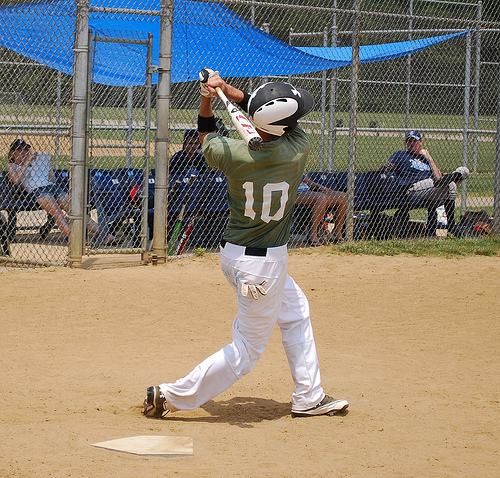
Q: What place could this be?
A: It is a field.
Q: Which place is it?
A: It is a field.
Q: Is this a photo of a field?
A: Yes, it is showing a field.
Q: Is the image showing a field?
A: Yes, it is showing a field.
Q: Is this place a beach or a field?
A: It is a field.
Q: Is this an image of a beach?
A: No, the picture is showing a field.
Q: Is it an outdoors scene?
A: Yes, it is outdoors.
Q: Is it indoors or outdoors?
A: It is outdoors.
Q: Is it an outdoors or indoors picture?
A: It is outdoors.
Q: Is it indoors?
A: No, it is outdoors.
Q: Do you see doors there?
A: Yes, there is a door.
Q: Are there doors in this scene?
A: Yes, there is a door.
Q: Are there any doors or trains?
A: Yes, there is a door.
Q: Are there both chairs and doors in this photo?
A: No, there is a door but no chairs.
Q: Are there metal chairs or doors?
A: Yes, there is a metal door.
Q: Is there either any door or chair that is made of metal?
A: Yes, the door is made of metal.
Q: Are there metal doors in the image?
A: Yes, there is a metal door.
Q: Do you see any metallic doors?
A: Yes, there is a metal door.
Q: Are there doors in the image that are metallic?
A: Yes, there is a door that is metallic.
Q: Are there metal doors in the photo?
A: Yes, there is a door that is made of metal.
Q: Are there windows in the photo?
A: No, there are no windows.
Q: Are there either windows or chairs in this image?
A: No, there are no windows or chairs.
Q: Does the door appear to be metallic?
A: Yes, the door is metallic.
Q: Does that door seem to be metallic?
A: Yes, the door is metallic.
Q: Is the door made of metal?
A: Yes, the door is made of metal.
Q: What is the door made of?
A: The door is made of metal.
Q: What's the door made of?
A: The door is made of metal.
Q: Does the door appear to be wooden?
A: No, the door is metallic.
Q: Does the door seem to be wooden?
A: No, the door is metallic.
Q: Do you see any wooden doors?
A: No, there is a door but it is metallic.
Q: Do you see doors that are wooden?
A: No, there is a door but it is metallic.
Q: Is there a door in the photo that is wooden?
A: No, there is a door but it is metallic.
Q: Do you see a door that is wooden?
A: No, there is a door but it is metallic.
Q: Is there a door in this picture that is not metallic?
A: No, there is a door but it is metallic.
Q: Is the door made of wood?
A: No, the door is made of metal.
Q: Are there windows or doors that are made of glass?
A: No, there is a door but it is made of metal.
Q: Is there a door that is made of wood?
A: No, there is a door but it is made of metal.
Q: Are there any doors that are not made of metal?
A: No, there is a door but it is made of metal.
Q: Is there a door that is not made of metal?
A: No, there is a door but it is made of metal.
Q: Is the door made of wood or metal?
A: The door is made of metal.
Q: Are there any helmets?
A: Yes, there is a helmet.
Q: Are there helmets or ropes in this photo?
A: Yes, there is a helmet.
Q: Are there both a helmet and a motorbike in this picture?
A: No, there is a helmet but no motorcycles.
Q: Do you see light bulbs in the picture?
A: No, there are no light bulbs.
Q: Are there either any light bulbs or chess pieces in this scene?
A: No, there are no light bulbs or chess pieces.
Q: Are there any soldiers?
A: No, there are no soldiers.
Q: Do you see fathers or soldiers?
A: No, there are no soldiers or fathers.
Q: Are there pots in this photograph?
A: No, there are no pots.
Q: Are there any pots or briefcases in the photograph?
A: No, there are no pots or briefcases.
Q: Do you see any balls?
A: No, there are no balls.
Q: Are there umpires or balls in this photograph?
A: No, there are no balls or umpires.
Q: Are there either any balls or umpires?
A: No, there are no balls or umpires.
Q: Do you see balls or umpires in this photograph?
A: No, there are no balls or umpires.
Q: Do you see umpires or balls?
A: No, there are no balls or umpires.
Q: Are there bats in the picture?
A: Yes, there is a bat.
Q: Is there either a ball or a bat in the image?
A: Yes, there is a bat.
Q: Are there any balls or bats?
A: Yes, there is a bat.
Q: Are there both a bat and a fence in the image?
A: Yes, there are both a bat and a fence.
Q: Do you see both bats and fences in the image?
A: Yes, there are both a bat and a fence.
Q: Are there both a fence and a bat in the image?
A: Yes, there are both a bat and a fence.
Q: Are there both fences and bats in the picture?
A: Yes, there are both a bat and a fence.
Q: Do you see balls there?
A: No, there are no balls.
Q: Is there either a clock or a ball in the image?
A: No, there are no balls or clocks.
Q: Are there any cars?
A: No, there are no cars.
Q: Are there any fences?
A: Yes, there is a fence.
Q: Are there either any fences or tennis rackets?
A: Yes, there is a fence.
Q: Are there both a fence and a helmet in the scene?
A: Yes, there are both a fence and a helmet.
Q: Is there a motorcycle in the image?
A: No, there are no motorcycles.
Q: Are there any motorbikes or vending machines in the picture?
A: No, there are no motorbikes or vending machines.